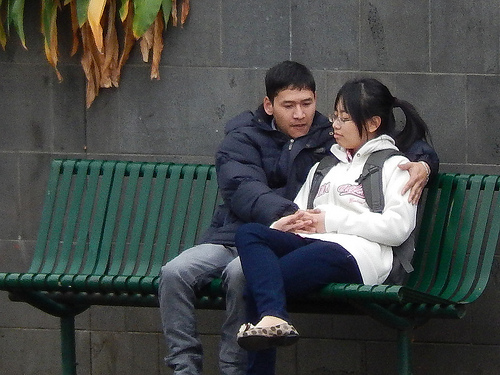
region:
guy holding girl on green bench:
[35, 50, 480, 372]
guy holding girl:
[175, 55, 437, 370]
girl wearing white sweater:
[317, 70, 438, 295]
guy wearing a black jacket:
[222, 38, 328, 219]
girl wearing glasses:
[326, 68, 421, 155]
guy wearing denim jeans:
[163, 40, 311, 372]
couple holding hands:
[163, 37, 438, 372]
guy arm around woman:
[215, 48, 442, 369]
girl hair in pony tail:
[323, 73, 433, 158]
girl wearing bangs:
[323, 73, 428, 155]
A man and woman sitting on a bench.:
[120, 57, 456, 367]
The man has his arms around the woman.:
[215, 41, 445, 256]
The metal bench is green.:
[1, 130, 496, 371]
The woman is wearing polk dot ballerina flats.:
[230, 308, 315, 349]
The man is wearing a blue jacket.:
[195, 118, 341, 239]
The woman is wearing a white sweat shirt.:
[276, 126, 422, 287]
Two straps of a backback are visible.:
[298, 142, 384, 219]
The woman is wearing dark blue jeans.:
[240, 220, 347, 320]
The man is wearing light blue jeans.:
[153, 230, 254, 372]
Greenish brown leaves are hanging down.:
[2, 3, 205, 113]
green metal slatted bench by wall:
[39, 150, 147, 301]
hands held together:
[281, 195, 327, 240]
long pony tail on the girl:
[389, 79, 431, 150]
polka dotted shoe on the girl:
[227, 308, 307, 353]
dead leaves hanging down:
[71, 23, 163, 100]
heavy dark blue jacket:
[205, 103, 282, 225]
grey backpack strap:
[357, 145, 401, 222]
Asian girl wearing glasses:
[325, 76, 398, 168]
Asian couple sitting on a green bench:
[216, 60, 427, 341]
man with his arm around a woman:
[217, 52, 457, 248]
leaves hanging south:
[0, 0, 192, 113]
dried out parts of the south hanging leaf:
[68, 25, 169, 111]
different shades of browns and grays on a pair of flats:
[234, 320, 299, 352]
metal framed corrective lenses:
[325, 109, 350, 123]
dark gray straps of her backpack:
[303, 148, 399, 214]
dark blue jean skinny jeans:
[233, 221, 363, 323]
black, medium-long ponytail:
[387, 91, 429, 152]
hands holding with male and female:
[271, 207, 323, 235]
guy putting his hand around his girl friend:
[395, 159, 431, 206]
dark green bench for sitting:
[0, 156, 499, 322]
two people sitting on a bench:
[104, 57, 457, 367]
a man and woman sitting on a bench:
[182, 67, 422, 229]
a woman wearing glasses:
[324, 75, 425, 147]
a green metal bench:
[18, 173, 490, 284]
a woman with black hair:
[313, 69, 421, 164]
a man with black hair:
[263, 56, 314, 155]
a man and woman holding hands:
[228, 62, 405, 247]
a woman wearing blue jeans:
[257, 77, 412, 299]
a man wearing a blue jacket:
[210, 44, 327, 243]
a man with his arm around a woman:
[226, 72, 451, 175]